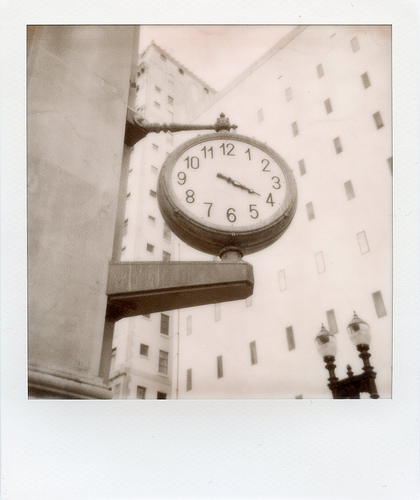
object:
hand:
[215, 171, 262, 198]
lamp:
[345, 308, 372, 352]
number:
[270, 173, 281, 190]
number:
[219, 138, 234, 158]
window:
[370, 109, 385, 130]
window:
[284, 323, 297, 356]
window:
[214, 352, 224, 381]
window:
[248, 337, 258, 367]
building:
[164, 28, 396, 403]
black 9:
[176, 169, 188, 187]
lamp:
[314, 319, 338, 361]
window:
[333, 135, 344, 155]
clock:
[155, 131, 297, 257]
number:
[202, 201, 215, 217]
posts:
[357, 351, 380, 397]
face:
[170, 139, 287, 230]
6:
[224, 208, 238, 224]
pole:
[326, 360, 340, 400]